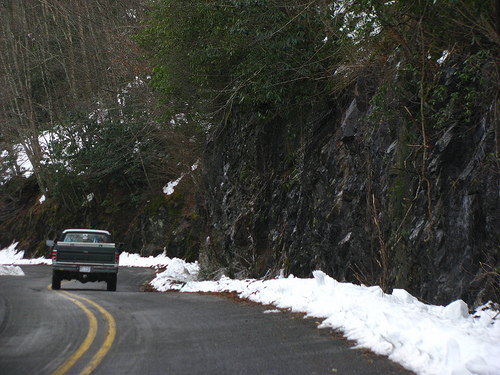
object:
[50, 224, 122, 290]
truck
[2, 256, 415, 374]
road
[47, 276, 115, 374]
lines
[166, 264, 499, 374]
cumpls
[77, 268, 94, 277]
license plate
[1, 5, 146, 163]
trees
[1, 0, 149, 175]
leaves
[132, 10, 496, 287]
trees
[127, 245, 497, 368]
sides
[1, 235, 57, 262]
snow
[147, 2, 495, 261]
leaves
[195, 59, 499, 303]
rocks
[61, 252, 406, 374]
right road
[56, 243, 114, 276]
space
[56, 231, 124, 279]
back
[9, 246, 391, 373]
snowing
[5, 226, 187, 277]
downhill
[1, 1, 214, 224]
cliff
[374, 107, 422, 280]
vines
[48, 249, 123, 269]
braking lights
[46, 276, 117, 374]
yellow line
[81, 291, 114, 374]
yellow line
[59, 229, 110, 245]
windshield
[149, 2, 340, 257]
tree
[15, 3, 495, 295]
hillside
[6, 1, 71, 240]
left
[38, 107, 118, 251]
trees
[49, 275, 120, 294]
tires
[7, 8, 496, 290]
forest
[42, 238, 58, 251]
mirror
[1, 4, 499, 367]
picture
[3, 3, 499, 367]
daytime